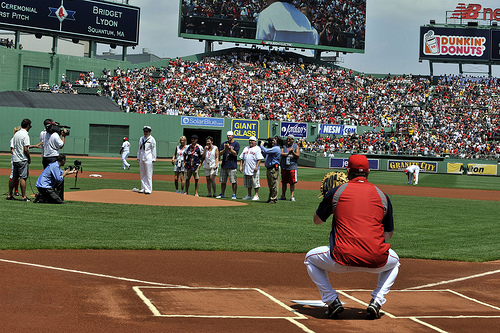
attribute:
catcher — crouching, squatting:
[301, 151, 400, 318]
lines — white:
[0, 255, 499, 328]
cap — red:
[345, 153, 370, 173]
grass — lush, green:
[1, 157, 497, 263]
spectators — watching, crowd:
[35, 50, 495, 159]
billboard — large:
[1, 1, 141, 51]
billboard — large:
[176, 1, 366, 57]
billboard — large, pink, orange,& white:
[417, 22, 497, 66]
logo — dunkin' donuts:
[423, 29, 486, 57]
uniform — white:
[135, 135, 157, 194]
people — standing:
[172, 129, 302, 205]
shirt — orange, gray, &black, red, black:
[315, 178, 395, 272]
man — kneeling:
[29, 155, 75, 206]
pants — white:
[304, 245, 401, 308]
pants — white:
[117, 151, 129, 168]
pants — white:
[136, 159, 153, 192]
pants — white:
[412, 165, 420, 185]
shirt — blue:
[33, 162, 69, 188]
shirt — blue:
[258, 142, 282, 167]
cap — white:
[246, 133, 259, 143]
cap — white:
[223, 130, 239, 137]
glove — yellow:
[319, 170, 345, 191]